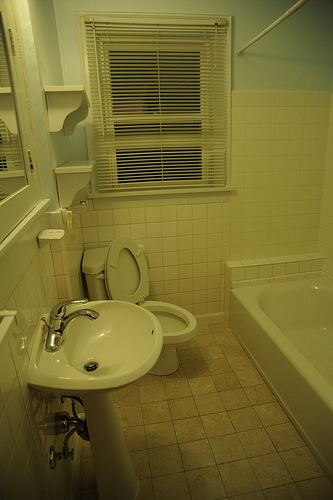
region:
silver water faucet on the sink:
[47, 290, 117, 369]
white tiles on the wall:
[159, 222, 222, 253]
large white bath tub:
[238, 289, 332, 412]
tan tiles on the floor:
[176, 392, 233, 468]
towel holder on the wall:
[60, 205, 84, 251]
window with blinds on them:
[82, 12, 229, 205]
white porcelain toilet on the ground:
[91, 239, 217, 370]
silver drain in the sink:
[72, 348, 107, 376]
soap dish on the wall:
[37, 219, 76, 253]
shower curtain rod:
[238, 5, 293, 84]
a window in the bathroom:
[78, 11, 230, 200]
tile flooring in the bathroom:
[173, 394, 265, 447]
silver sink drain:
[64, 346, 108, 379]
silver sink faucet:
[26, 292, 118, 377]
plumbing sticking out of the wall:
[40, 386, 102, 478]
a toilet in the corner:
[64, 234, 213, 409]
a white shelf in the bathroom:
[48, 131, 112, 227]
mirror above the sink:
[0, 8, 82, 198]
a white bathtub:
[211, 242, 332, 453]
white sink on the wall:
[30, 282, 180, 416]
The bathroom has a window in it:
[83, 2, 242, 196]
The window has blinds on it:
[93, 30, 196, 189]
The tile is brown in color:
[175, 428, 237, 478]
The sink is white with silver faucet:
[44, 300, 164, 483]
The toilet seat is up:
[88, 241, 241, 369]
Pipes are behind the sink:
[45, 403, 91, 484]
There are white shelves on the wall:
[43, 76, 100, 212]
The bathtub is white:
[239, 269, 330, 405]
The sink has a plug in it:
[82, 356, 97, 368]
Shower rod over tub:
[249, 18, 315, 54]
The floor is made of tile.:
[176, 393, 261, 477]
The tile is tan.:
[186, 403, 250, 477]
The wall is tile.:
[167, 216, 215, 252]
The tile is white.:
[155, 215, 210, 265]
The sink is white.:
[45, 299, 167, 394]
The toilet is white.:
[87, 235, 203, 347]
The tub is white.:
[236, 287, 331, 456]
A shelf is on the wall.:
[50, 156, 97, 210]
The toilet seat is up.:
[97, 229, 201, 341]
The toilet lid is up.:
[98, 232, 201, 344]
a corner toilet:
[74, 237, 200, 377]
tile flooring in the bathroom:
[133, 423, 244, 477]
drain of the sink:
[74, 353, 102, 377]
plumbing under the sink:
[30, 397, 111, 467]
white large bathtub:
[207, 239, 331, 461]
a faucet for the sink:
[21, 272, 99, 375]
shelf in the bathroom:
[50, 130, 114, 221]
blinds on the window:
[71, 9, 253, 207]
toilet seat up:
[96, 227, 172, 313]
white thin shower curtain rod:
[229, 0, 315, 67]